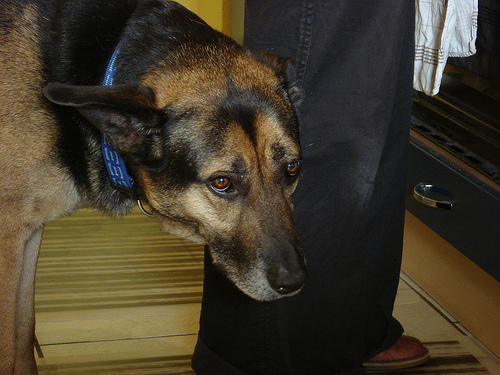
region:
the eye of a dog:
[213, 176, 233, 193]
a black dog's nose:
[267, 269, 309, 298]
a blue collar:
[94, 41, 135, 196]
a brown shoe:
[367, 332, 433, 369]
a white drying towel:
[412, 1, 482, 101]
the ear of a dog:
[29, 80, 162, 127]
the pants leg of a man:
[190, 0, 391, 373]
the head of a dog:
[122, 71, 316, 303]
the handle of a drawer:
[413, 184, 450, 219]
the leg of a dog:
[17, 232, 52, 374]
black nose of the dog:
[262, 235, 339, 289]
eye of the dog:
[196, 151, 244, 213]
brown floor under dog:
[68, 256, 155, 341]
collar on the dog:
[82, 73, 140, 206]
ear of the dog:
[53, 66, 167, 153]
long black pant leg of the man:
[326, 40, 398, 244]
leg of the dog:
[12, 224, 56, 355]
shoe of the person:
[379, 321, 436, 372]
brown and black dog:
[34, 16, 270, 203]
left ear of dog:
[243, 36, 307, 116]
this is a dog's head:
[38, 62, 314, 306]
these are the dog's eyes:
[203, 158, 304, 200]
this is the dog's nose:
[256, 244, 312, 291]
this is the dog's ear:
[30, 75, 165, 151]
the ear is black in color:
[88, 105, 110, 115]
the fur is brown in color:
[5, 93, 31, 175]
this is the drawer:
[413, 135, 498, 270]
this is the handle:
[410, 175, 455, 211]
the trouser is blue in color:
[312, 39, 387, 121]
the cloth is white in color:
[426, 15, 461, 30]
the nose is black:
[269, 261, 296, 293]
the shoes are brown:
[370, 332, 422, 370]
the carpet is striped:
[43, 232, 199, 372]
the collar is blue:
[98, 120, 135, 198]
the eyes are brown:
[202, 156, 298, 191]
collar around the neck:
[81, 19, 133, 216]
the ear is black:
[50, 90, 158, 165]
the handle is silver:
[407, 180, 457, 220]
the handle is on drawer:
[395, 148, 497, 310]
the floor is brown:
[411, 232, 481, 323]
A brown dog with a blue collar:
[36, 3, 368, 318]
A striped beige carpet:
[70, 230, 165, 364]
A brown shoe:
[362, 305, 440, 369]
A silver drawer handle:
[405, 163, 470, 228]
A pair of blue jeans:
[291, 10, 415, 345]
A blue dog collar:
[90, 4, 154, 219]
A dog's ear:
[34, 72, 180, 156]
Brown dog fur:
[2, 45, 44, 223]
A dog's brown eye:
[192, 154, 249, 203]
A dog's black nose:
[250, 238, 319, 303]